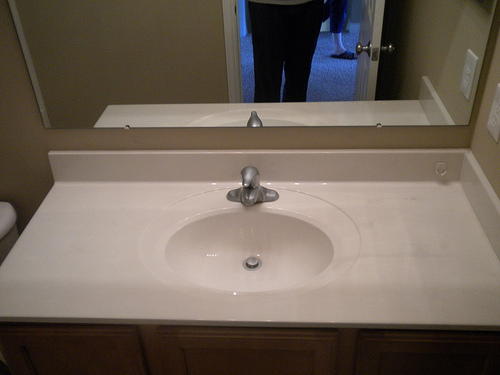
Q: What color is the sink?
A: White.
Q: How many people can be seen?
A: Two.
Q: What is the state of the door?
A: Open.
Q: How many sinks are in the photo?
A: One.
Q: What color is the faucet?
A: Silver.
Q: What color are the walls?
A: Tan.